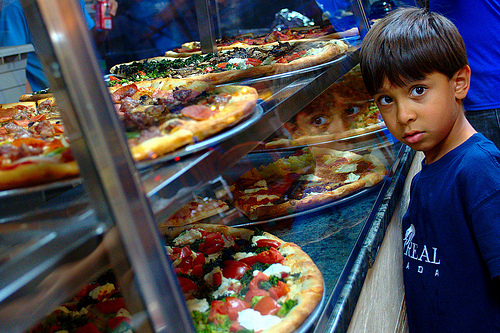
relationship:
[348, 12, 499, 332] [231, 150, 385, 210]
boy next to pizza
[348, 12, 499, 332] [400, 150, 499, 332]
boy wearing a blue shirt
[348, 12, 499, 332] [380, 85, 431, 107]
boy has brown eyes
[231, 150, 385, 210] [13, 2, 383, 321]
pizza on display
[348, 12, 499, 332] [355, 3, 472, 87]
boy has short hair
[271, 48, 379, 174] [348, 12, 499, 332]
reflection of boy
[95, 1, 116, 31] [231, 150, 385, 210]
soda can behind pizza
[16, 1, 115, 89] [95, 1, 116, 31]
person holding soda can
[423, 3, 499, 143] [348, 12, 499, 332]
person behind boy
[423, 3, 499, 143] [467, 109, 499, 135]
person wearing jeans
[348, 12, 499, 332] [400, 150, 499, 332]
boy wearing blue shirt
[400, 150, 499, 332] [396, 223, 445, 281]
shirt has logo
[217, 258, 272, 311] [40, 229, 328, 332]
tomatoes on top of pizza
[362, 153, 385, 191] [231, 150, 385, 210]
crust of pizza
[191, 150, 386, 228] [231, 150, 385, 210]
tray under pizza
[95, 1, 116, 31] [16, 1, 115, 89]
soda can held by person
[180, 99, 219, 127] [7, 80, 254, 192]
pepperoni on top of pizza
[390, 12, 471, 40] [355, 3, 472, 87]
light reflected on hair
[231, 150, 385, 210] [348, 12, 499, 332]
pizza next to boy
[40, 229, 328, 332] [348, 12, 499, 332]
pizza next to boy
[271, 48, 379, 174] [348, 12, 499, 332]
reflection in window of boy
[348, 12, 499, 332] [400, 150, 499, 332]
boy wears a shirt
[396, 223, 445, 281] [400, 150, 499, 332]
logo on shirt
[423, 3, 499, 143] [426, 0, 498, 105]
person wearing a bright shirt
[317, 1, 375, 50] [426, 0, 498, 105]
reflection of bright shirt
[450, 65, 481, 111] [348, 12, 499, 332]
ear of a boy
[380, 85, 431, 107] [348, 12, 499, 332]
eyes of boy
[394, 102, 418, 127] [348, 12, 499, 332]
nose of boy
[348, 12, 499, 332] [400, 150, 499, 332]
boy wearing a shirt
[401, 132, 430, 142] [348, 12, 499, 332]
lips of boy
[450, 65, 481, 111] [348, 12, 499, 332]
ear of boy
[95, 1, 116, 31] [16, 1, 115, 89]
soda can being held by person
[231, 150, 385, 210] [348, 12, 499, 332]
pizza in front of boy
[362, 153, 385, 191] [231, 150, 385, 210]
crust on pizza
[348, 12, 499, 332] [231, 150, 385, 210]
boy standing next to pizza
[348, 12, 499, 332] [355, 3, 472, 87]
boy has black hair